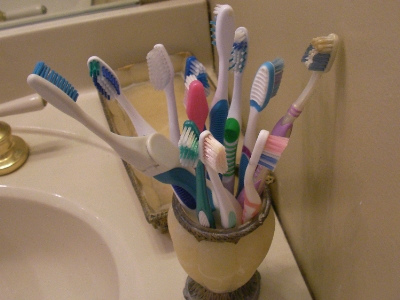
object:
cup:
[166, 181, 275, 295]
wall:
[307, 3, 398, 242]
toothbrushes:
[20, 63, 110, 135]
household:
[0, 4, 399, 300]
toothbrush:
[241, 56, 283, 151]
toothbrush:
[86, 55, 153, 134]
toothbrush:
[237, 130, 293, 215]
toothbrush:
[219, 25, 250, 192]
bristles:
[236, 66, 242, 70]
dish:
[94, 34, 337, 226]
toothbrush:
[143, 40, 179, 138]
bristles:
[147, 53, 153, 58]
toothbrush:
[197, 130, 242, 227]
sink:
[4, 20, 315, 297]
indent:
[3, 194, 122, 298]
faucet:
[0, 91, 46, 176]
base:
[1, 120, 30, 176]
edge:
[208, 3, 218, 48]